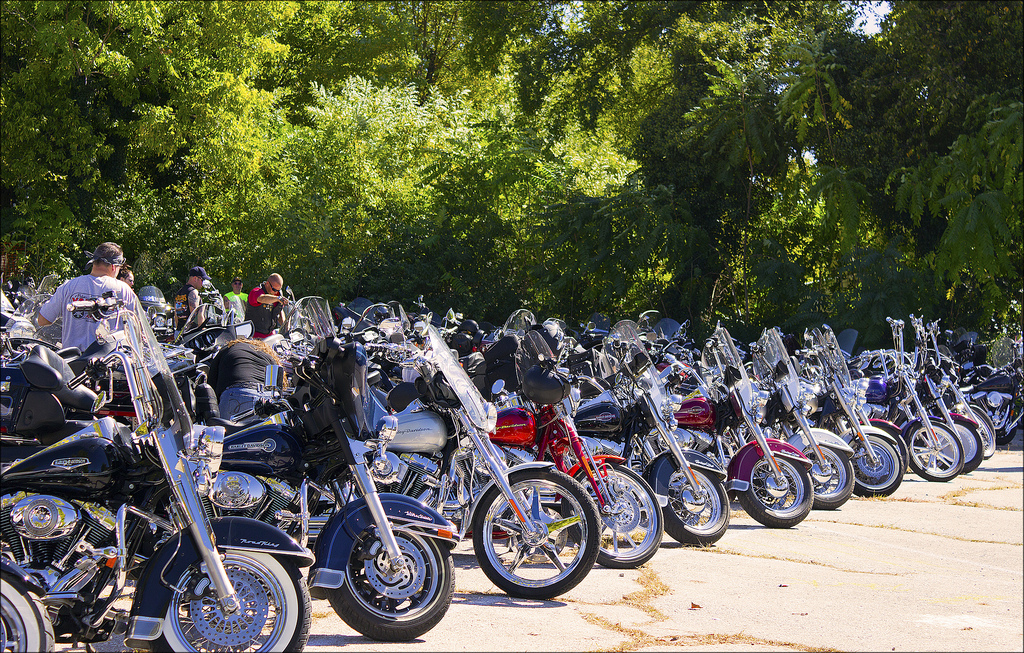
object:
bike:
[368, 303, 618, 612]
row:
[403, 290, 791, 514]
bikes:
[3, 303, 341, 652]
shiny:
[149, 421, 185, 482]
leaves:
[299, 78, 331, 102]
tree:
[627, 59, 785, 336]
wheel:
[470, 460, 605, 601]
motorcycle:
[392, 311, 670, 573]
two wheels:
[636, 447, 733, 551]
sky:
[855, 8, 880, 25]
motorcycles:
[177, 341, 464, 639]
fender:
[545, 413, 602, 468]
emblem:
[30, 504, 53, 526]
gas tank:
[0, 433, 132, 502]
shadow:
[451, 586, 569, 613]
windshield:
[102, 313, 153, 411]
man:
[25, 240, 151, 363]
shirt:
[36, 272, 146, 357]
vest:
[247, 294, 278, 336]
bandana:
[185, 267, 204, 281]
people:
[166, 268, 218, 327]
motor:
[354, 447, 449, 502]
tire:
[733, 449, 818, 532]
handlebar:
[345, 348, 452, 402]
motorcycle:
[681, 312, 816, 533]